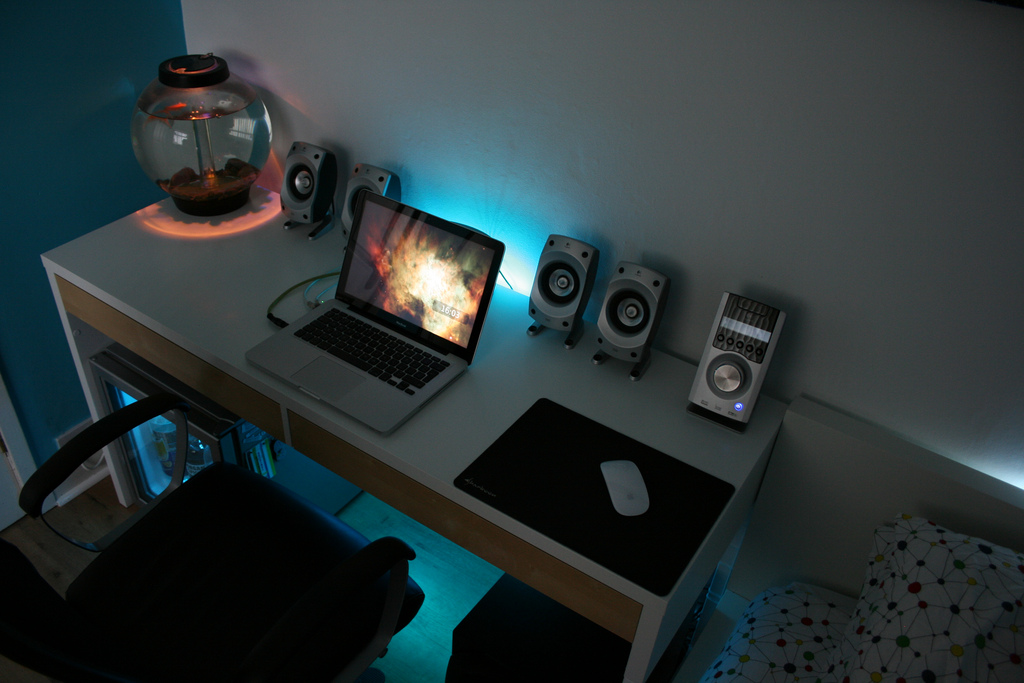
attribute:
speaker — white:
[559, 214, 659, 325]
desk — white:
[134, 140, 767, 551]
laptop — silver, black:
[233, 186, 532, 446]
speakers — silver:
[510, 225, 671, 379]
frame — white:
[739, 402, 1005, 604]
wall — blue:
[8, 18, 220, 408]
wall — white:
[166, 22, 1018, 431]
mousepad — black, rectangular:
[477, 402, 732, 614]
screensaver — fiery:
[345, 212, 525, 396]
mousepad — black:
[460, 381, 744, 604]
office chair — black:
[2, 404, 441, 677]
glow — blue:
[432, 197, 558, 314]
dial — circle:
[704, 342, 761, 418]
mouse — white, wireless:
[587, 448, 665, 541]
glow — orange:
[132, 203, 327, 247]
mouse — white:
[587, 432, 667, 543]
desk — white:
[38, 138, 786, 679]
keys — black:
[294, 307, 435, 387]